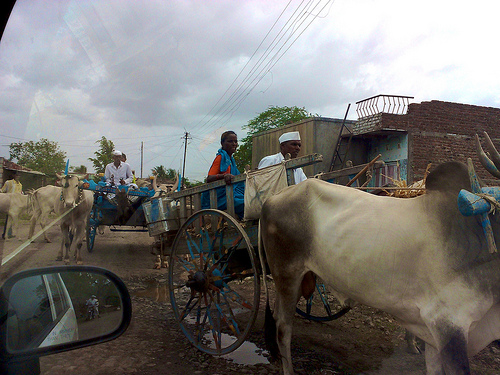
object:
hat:
[278, 130, 302, 145]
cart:
[139, 156, 396, 361]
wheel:
[167, 208, 262, 357]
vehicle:
[8, 269, 78, 353]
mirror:
[8, 271, 126, 353]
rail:
[383, 96, 408, 115]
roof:
[356, 95, 500, 131]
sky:
[23, 0, 500, 85]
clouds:
[28, 25, 191, 102]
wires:
[220, 1, 326, 105]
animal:
[258, 160, 497, 375]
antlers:
[473, 124, 500, 182]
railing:
[179, 179, 234, 229]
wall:
[412, 103, 462, 160]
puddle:
[200, 329, 274, 367]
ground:
[119, 339, 181, 369]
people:
[200, 130, 244, 219]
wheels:
[292, 279, 353, 325]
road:
[36, 223, 157, 276]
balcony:
[355, 93, 410, 131]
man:
[257, 130, 307, 184]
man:
[104, 150, 134, 187]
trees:
[10, 134, 67, 176]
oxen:
[52, 172, 91, 266]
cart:
[81, 173, 173, 254]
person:
[85, 294, 99, 307]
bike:
[83, 300, 99, 321]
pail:
[141, 196, 179, 238]